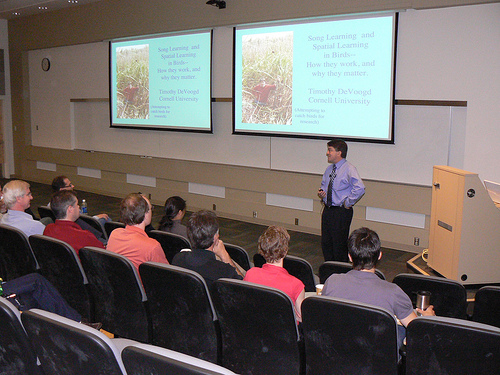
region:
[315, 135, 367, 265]
Man lecturing a group of people.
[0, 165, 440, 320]
People listening to the lecture.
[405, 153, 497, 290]
Podium can be used.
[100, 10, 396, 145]
Slide show up on the wall.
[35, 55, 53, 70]
Clock on the wall.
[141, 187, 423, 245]
Outlets on the wall.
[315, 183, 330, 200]
Man has remote in hand for the slide show.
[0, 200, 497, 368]
Seats in the lecture hall.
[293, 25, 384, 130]
Writing on the slide show.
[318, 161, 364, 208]
Man wearing a dress shirt and tie.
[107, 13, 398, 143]
two screens on wall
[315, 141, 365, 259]
man in front of room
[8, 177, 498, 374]
three rows of seats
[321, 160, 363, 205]
tie on purple shirt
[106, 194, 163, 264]
man in orange shirt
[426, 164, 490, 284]
front of tan podium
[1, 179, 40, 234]
man with gray hair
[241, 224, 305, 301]
woman in short sleeved shirt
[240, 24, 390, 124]
image on projector screen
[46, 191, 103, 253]
man in red shirt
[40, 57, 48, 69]
Analog wall clock.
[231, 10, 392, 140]
Digital projector screen on wall.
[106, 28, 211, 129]
Digital projector screen on wall.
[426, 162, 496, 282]
Podium with computer equipment.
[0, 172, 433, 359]
Seated attentive audience members.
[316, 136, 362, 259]
Speaker delivering a presentation.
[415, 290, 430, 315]
Insulated metal coffee thermos.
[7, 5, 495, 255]
Tan and white faceted wall.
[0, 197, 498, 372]
Cushioned retractable audience seating.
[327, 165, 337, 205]
Thin dress tie of shiny material.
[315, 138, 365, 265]
man giving a presentation.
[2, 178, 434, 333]
members of the audience listening to the presentation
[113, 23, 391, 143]
two projection screens on the wall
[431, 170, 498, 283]
a wooden podium on the right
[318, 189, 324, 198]
the remote control for the slides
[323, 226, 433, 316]
the person holding the coffee mug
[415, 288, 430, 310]
silver coffee mug with black top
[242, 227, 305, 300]
woman with the red shirt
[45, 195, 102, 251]
man with the red shirt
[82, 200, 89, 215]
a plastic water bottle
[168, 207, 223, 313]
man wearing black shirt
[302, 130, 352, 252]
man speaking in front of people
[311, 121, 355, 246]
man wearing blue shirt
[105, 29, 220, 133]
projection screen with picture and writing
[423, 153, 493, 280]
podium made of wood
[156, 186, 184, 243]
man with pony tail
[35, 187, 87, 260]
man wearing red shirt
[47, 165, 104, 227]
man holding water bottle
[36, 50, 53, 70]
clock on wall in corner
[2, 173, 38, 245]
man with white hair